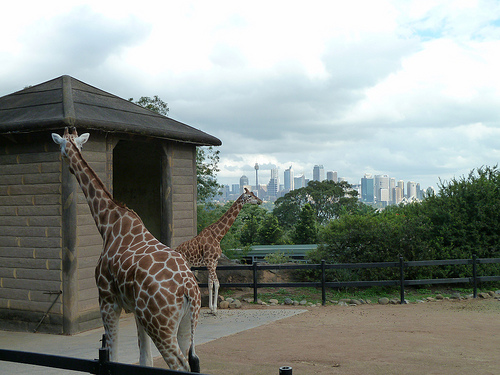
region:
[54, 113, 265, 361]
Two giraffes at a zoo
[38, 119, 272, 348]
Two giraffes near a structure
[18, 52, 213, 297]
Giraffes near building at zoo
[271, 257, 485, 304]
Wooden fence around giraffe exhibit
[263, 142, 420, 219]
Tall buildings in the distance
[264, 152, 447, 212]
Skyline in the distance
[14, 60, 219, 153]
Roof of structure is brown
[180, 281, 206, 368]
Giraffe has a long tail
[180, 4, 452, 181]
Mostly cloudy sky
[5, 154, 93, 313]
Structure made of cement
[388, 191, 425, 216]
the opera house is behind the zoo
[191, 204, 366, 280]
a train is going by the animals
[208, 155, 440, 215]
the city is across from the enclosure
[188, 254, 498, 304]
a black wooden fence is around the pen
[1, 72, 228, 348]
the giraffe house has an arched doorway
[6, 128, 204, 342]
the house is made of cement bricks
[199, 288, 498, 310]
rocks are placed below the fence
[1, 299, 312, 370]
the house has a poured cement patio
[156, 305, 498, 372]
the pen has a dirt floor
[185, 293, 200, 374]
the giraffe's tail has long black hair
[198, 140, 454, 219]
a city sky line.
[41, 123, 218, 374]
a giraffe near a small structure.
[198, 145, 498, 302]
a forest filled with trees.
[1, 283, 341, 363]
a paved cement platform.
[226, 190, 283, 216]
a tall giraffe's head.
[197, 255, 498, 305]
a wooden fence near a hill.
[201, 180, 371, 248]
a forest near a river.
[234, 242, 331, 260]
a river near a forest.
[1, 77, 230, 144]
the roof on a small building.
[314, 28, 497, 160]
a large gray cloud.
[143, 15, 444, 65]
this is the sky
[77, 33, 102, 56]
the sky is blue in color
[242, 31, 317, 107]
the sky has some clouds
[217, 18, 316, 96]
the clouds are white in color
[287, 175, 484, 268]
these are several trees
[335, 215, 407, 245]
the leaves are green in color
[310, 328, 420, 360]
the sand is brown in color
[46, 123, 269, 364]
these are two giraffes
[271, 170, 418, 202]
these are some buildings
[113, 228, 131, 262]
the fur is brown in color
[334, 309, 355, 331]
part of a floor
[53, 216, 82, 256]
edge of a house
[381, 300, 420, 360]
par of a ground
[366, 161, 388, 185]
part of a building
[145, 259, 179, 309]
part of a thigh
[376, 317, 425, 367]
part of a ground